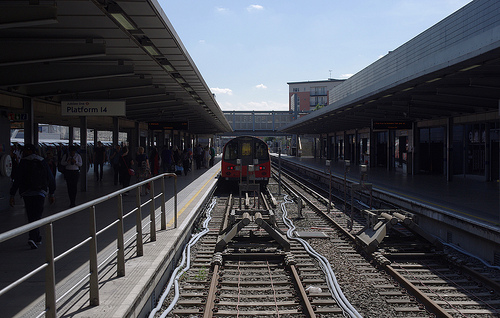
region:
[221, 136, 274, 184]
a train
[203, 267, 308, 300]
the train tracks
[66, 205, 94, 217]
a metal railing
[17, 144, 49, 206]
a person walking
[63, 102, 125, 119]
a sign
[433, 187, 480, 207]
the sidewalk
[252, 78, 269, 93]
a cloud in the sky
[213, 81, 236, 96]
the cloud is white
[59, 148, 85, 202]
a person walking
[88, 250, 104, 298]
the pole is grey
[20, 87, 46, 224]
This is a pole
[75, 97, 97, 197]
This is a pole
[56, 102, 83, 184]
This is a pole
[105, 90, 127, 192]
This is a pole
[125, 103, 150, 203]
This is a pole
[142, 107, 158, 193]
This is a pole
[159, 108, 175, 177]
This is a pole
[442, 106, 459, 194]
This is a pole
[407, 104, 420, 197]
This is a pole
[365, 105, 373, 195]
This is a pole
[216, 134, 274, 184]
this is a train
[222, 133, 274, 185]
the train is motionless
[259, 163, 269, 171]
the light is on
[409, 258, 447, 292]
these are the rails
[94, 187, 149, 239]
this is the fence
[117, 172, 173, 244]
the fence is metallic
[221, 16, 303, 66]
this is the sky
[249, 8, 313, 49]
the sky is clear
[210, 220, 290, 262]
the rails are metallic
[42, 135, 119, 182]
these are the passengers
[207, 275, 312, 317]
train tracks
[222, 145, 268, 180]
a train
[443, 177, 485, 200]
the sidewalk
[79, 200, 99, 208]
the railing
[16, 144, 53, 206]
a person walking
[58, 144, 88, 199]
a person walking on the sidewalk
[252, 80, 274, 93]
a cloud in the sky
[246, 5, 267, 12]
the cloud is white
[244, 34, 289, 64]
the sky is clear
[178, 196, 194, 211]
a yellow line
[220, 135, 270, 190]
the train on the track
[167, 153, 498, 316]
the train tracks at the station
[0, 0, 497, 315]
the train station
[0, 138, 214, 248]
the people on the walkway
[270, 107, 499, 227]
the empty walkway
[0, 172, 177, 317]
the railing on the walkway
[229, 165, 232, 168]
the red light on the train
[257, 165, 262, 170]
the red light on the train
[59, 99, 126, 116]
the sign at the station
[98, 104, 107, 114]
the number 14 on the sign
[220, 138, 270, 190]
The back of a train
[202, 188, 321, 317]
Metal railroad tracks behind a train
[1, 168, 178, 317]
A metal rail near train tracks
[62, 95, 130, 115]
A sign in a train station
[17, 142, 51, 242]
A man walking in a station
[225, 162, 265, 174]
Tail lights on a train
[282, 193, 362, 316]
Electrical cords near a train track